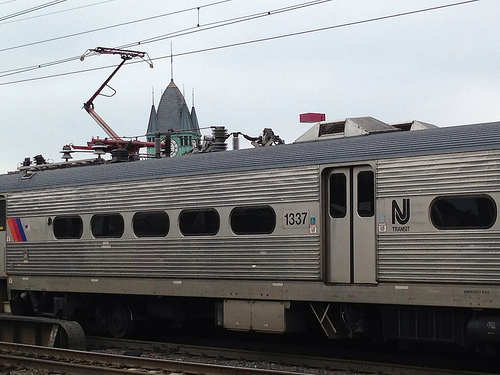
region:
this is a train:
[0, 117, 498, 323]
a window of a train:
[86, 203, 128, 245]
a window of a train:
[132, 200, 177, 249]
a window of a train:
[172, 199, 222, 248]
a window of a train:
[228, 196, 279, 251]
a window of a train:
[428, 185, 497, 232]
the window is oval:
[230, 197, 284, 242]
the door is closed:
[311, 150, 386, 293]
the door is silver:
[318, 160, 383, 292]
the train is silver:
[13, 163, 490, 323]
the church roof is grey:
[145, 41, 206, 150]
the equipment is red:
[57, 34, 160, 159]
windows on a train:
[33, 202, 279, 248]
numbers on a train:
[281, 202, 311, 232]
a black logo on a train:
[389, 182, 414, 233]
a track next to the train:
[83, 326, 205, 363]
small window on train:
[44, 203, 86, 244]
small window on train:
[84, 201, 129, 249]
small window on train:
[132, 195, 170, 252]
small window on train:
[172, 199, 224, 247]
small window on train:
[217, 195, 274, 245]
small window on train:
[324, 163, 352, 230]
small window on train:
[350, 166, 381, 223]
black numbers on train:
[278, 212, 323, 239]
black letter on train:
[382, 188, 420, 239]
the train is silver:
[0, 121, 496, 348]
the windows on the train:
[0, 122, 497, 350]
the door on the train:
[0, 120, 496, 357]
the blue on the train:
[0, 120, 498, 352]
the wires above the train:
[0, 0, 499, 350]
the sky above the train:
[0, 0, 497, 364]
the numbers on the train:
[0, 122, 496, 360]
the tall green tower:
[145, 36, 200, 158]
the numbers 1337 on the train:
[0, 121, 498, 351]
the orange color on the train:
[0, 120, 497, 357]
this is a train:
[3, 120, 498, 351]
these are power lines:
[2, 0, 492, 82]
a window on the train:
[48, 209, 83, 248]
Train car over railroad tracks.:
[1, 117, 499, 352]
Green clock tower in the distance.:
[146, 42, 206, 157]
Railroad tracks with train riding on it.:
[1, 318, 499, 370]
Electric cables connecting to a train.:
[1, 2, 496, 87]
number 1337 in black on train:
[278, 207, 318, 232]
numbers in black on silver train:
[279, 203, 314, 237]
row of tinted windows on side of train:
[32, 164, 314, 266]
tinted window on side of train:
[227, 203, 279, 237]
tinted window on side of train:
[177, 202, 223, 244]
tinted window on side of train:
[129, 204, 170, 248]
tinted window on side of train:
[89, 208, 125, 247]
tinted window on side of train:
[48, 210, 83, 247]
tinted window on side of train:
[422, 190, 497, 234]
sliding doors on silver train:
[312, 149, 384, 296]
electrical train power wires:
[0, 3, 492, 93]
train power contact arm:
[60, 43, 167, 161]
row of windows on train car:
[43, 183, 498, 247]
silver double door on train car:
[314, 157, 390, 292]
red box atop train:
[294, 108, 331, 130]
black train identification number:
[279, 206, 316, 232]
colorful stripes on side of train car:
[5, 213, 29, 245]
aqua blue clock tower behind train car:
[144, 41, 206, 157]